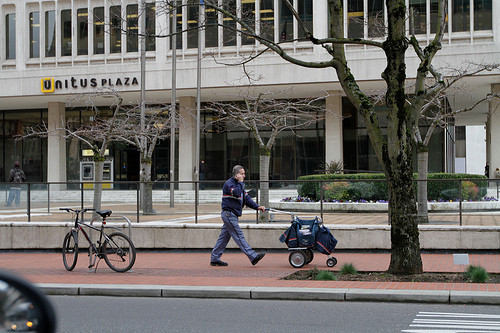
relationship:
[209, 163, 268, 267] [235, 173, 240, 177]
man on phone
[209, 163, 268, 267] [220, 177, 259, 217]
man wearing jacket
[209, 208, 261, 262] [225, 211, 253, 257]
pants have stripe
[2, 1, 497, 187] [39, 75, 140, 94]
building has sign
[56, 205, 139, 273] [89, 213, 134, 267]
bike chained to post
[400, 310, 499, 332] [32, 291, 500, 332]
lettering on road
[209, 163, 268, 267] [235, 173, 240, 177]
man talking on phone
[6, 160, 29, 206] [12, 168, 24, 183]
man with backpack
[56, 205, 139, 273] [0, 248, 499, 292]
bike parked on sidewalk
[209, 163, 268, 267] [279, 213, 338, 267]
man pushig mail stroller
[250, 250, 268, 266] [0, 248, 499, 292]
foot lifted off sidewalk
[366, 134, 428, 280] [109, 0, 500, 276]
trunk of tree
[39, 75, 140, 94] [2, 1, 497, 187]
sign on building